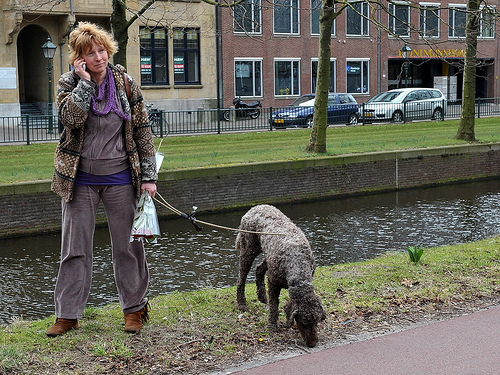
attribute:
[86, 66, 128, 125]
scarf — purple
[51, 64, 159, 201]
sweater — gray, patterned, brown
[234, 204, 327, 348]
dog — poodle, gray, walking, black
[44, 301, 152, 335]
boots — brown, suede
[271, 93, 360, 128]
car — blue, parked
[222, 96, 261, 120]
motorcycle — black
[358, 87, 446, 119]
van — silver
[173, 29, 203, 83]
window — large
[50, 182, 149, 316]
pants — gray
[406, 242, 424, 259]
plant — small, green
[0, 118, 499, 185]
grass — green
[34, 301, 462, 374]
spot — brown, bald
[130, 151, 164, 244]
paper — green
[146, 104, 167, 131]
bike — black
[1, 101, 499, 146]
fence — silver, metal